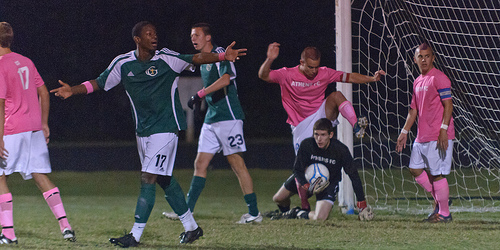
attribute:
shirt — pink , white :
[409, 67, 456, 142]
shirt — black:
[292, 135, 365, 206]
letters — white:
[309, 151, 338, 168]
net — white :
[348, 1, 499, 213]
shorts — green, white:
[133, 132, 178, 177]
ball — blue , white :
[303, 162, 330, 189]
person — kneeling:
[269, 117, 379, 229]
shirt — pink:
[405, 70, 459, 143]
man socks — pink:
[0, 31, 83, 248]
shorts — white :
[4, 133, 51, 173]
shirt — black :
[314, 149, 338, 169]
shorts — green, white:
[122, 126, 297, 218]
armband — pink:
[81, 80, 94, 94]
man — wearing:
[256, 32, 359, 202]